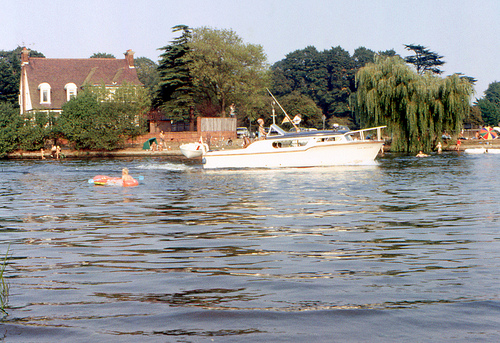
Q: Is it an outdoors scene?
A: Yes, it is outdoors.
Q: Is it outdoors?
A: Yes, it is outdoors.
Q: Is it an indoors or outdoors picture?
A: It is outdoors.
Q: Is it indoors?
A: No, it is outdoors.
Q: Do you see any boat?
A: Yes, there is a boat.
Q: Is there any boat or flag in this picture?
A: Yes, there is a boat.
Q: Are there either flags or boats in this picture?
A: Yes, there is a boat.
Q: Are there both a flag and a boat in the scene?
A: No, there is a boat but no flags.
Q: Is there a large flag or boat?
A: Yes, there is a large boat.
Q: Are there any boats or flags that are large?
A: Yes, the boat is large.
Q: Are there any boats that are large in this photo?
A: Yes, there is a large boat.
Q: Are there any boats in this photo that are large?
A: Yes, there is a boat that is large.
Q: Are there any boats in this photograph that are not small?
A: Yes, there is a large boat.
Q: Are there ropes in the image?
A: No, there are no ropes.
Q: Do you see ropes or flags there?
A: No, there are no ropes or flags.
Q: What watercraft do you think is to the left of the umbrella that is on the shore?
A: The watercraft is a boat.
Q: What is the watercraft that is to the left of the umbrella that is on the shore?
A: The watercraft is a boat.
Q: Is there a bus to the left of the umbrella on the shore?
A: No, there is a boat to the left of the umbrella.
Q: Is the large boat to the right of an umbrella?
A: No, the boat is to the left of an umbrella.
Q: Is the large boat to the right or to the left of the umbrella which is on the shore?
A: The boat is to the left of the umbrella.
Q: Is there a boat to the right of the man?
A: Yes, there is a boat to the right of the man.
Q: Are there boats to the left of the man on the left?
A: No, the boat is to the right of the man.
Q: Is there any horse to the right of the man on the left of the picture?
A: No, there is a boat to the right of the man.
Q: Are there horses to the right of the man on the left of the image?
A: No, there is a boat to the right of the man.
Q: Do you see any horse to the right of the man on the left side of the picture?
A: No, there is a boat to the right of the man.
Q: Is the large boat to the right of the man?
A: Yes, the boat is to the right of the man.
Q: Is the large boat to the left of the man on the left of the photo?
A: No, the boat is to the right of the man.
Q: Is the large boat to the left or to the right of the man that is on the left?
A: The boat is to the right of the man.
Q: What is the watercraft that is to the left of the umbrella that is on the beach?
A: The watercraft is a boat.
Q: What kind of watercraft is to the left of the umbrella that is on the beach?
A: The watercraft is a boat.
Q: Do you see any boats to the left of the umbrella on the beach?
A: Yes, there is a boat to the left of the umbrella.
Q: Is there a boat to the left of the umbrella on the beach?
A: Yes, there is a boat to the left of the umbrella.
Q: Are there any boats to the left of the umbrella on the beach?
A: Yes, there is a boat to the left of the umbrella.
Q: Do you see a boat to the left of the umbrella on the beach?
A: Yes, there is a boat to the left of the umbrella.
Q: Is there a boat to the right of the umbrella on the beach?
A: No, the boat is to the left of the umbrella.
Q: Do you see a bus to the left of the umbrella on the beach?
A: No, there is a boat to the left of the umbrella.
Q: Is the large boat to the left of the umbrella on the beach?
A: Yes, the boat is to the left of the umbrella.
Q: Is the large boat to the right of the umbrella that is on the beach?
A: No, the boat is to the left of the umbrella.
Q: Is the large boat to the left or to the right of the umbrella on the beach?
A: The boat is to the left of the umbrella.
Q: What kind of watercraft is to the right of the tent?
A: The watercraft is a boat.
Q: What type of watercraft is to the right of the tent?
A: The watercraft is a boat.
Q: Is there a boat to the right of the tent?
A: Yes, there is a boat to the right of the tent.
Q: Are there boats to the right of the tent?
A: Yes, there is a boat to the right of the tent.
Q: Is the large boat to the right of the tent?
A: Yes, the boat is to the right of the tent.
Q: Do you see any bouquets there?
A: No, there are no bouquets.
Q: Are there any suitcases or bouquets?
A: No, there are no bouquets or suitcases.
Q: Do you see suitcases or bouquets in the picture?
A: No, there are no bouquets or suitcases.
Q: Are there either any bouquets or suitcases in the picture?
A: No, there are no bouquets or suitcases.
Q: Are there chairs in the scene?
A: No, there are no chairs.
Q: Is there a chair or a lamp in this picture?
A: No, there are no chairs or lamps.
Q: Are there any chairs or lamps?
A: No, there are no chairs or lamps.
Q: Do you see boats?
A: Yes, there is a boat.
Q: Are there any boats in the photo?
A: Yes, there is a boat.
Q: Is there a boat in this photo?
A: Yes, there is a boat.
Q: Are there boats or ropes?
A: Yes, there is a boat.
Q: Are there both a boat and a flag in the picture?
A: No, there is a boat but no flags.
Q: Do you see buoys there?
A: No, there are no buoys.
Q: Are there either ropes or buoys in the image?
A: No, there are no buoys or ropes.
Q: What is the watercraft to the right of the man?
A: The watercraft is a boat.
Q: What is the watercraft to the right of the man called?
A: The watercraft is a boat.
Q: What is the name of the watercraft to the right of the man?
A: The watercraft is a boat.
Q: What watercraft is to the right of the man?
A: The watercraft is a boat.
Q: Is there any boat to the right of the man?
A: Yes, there is a boat to the right of the man.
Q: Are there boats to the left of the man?
A: No, the boat is to the right of the man.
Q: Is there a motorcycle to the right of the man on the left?
A: No, there is a boat to the right of the man.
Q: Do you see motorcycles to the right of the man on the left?
A: No, there is a boat to the right of the man.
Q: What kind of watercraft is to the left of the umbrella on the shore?
A: The watercraft is a boat.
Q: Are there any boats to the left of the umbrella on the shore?
A: Yes, there is a boat to the left of the umbrella.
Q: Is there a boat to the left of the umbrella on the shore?
A: Yes, there is a boat to the left of the umbrella.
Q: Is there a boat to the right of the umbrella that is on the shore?
A: No, the boat is to the left of the umbrella.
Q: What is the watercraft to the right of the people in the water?
A: The watercraft is a boat.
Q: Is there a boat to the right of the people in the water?
A: Yes, there is a boat to the right of the people.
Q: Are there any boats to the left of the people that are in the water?
A: No, the boat is to the right of the people.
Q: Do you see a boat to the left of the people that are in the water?
A: No, the boat is to the right of the people.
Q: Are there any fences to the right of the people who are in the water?
A: No, there is a boat to the right of the people.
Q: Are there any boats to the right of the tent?
A: Yes, there is a boat to the right of the tent.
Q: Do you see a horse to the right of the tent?
A: No, there is a boat to the right of the tent.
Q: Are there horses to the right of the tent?
A: No, there is a boat to the right of the tent.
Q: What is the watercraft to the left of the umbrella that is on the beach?
A: The watercraft is a boat.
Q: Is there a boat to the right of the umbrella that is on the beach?
A: No, the boat is to the left of the umbrella.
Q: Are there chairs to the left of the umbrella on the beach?
A: No, there is a boat to the left of the umbrella.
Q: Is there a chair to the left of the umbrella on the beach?
A: No, there is a boat to the left of the umbrella.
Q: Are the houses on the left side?
A: Yes, the houses are on the left of the image.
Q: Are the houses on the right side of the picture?
A: No, the houses are on the left of the image.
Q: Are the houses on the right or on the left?
A: The houses are on the left of the image.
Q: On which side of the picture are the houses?
A: The houses are on the left of the image.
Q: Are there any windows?
A: Yes, there are windows.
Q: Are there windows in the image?
A: Yes, there are windows.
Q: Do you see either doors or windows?
A: Yes, there are windows.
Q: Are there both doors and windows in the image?
A: No, there are windows but no doors.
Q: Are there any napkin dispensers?
A: No, there are no napkin dispensers.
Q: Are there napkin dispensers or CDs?
A: No, there are no napkin dispensers or cds.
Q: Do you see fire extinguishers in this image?
A: No, there are no fire extinguishers.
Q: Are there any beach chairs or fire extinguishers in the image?
A: No, there are no fire extinguishers or beach chairs.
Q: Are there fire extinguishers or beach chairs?
A: No, there are no fire extinguishers or beach chairs.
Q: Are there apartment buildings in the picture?
A: No, there are no apartment buildings.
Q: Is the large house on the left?
A: Yes, the house is on the left of the image.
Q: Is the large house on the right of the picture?
A: No, the house is on the left of the image.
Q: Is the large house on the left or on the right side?
A: The house is on the left of the image.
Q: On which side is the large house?
A: The house is on the left of the image.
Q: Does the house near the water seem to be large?
A: Yes, the house is large.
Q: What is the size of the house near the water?
A: The house is large.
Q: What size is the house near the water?
A: The house is large.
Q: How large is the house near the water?
A: The house is large.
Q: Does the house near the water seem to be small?
A: No, the house is large.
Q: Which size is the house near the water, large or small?
A: The house is large.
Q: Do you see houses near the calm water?
A: Yes, there is a house near the water.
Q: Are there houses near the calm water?
A: Yes, there is a house near the water.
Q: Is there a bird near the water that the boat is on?
A: No, there is a house near the water.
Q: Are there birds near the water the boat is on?
A: No, there is a house near the water.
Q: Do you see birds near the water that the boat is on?
A: No, there is a house near the water.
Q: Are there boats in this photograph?
A: Yes, there is a boat.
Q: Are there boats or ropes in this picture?
A: Yes, there is a boat.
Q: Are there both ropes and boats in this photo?
A: No, there is a boat but no ropes.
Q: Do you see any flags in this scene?
A: No, there are no flags.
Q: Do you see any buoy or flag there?
A: No, there are no flags or buoys.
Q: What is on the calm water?
A: The boat is on the water.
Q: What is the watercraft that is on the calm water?
A: The watercraft is a boat.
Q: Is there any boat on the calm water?
A: Yes, there is a boat on the water.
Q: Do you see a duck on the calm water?
A: No, there is a boat on the water.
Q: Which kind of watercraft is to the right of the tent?
A: The watercraft is a boat.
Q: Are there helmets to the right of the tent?
A: No, there is a boat to the right of the tent.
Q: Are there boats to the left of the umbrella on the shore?
A: Yes, there is a boat to the left of the umbrella.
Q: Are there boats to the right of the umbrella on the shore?
A: No, the boat is to the left of the umbrella.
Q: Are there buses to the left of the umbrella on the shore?
A: No, there is a boat to the left of the umbrella.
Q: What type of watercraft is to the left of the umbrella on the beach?
A: The watercraft is a boat.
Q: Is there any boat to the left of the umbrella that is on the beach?
A: Yes, there is a boat to the left of the umbrella.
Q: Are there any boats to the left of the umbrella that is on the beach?
A: Yes, there is a boat to the left of the umbrella.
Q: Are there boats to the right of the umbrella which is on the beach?
A: No, the boat is to the left of the umbrella.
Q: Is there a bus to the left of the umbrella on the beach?
A: No, there is a boat to the left of the umbrella.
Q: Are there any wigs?
A: No, there are no wigs.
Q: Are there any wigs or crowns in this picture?
A: No, there are no wigs or crowns.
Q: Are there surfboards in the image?
A: No, there are no surfboards.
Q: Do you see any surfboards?
A: No, there are no surfboards.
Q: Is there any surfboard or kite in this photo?
A: No, there are no surfboards or kites.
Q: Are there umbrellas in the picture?
A: Yes, there is an umbrella.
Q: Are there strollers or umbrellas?
A: Yes, there is an umbrella.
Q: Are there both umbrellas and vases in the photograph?
A: No, there is an umbrella but no vases.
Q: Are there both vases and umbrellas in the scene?
A: No, there is an umbrella but no vases.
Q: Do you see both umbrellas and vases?
A: No, there is an umbrella but no vases.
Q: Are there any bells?
A: No, there are no bells.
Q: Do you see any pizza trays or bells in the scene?
A: No, there are no bells or pizza trays.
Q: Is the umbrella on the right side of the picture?
A: Yes, the umbrella is on the right of the image.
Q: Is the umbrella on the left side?
A: No, the umbrella is on the right of the image.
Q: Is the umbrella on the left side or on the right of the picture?
A: The umbrella is on the right of the image.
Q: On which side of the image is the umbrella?
A: The umbrella is on the right of the image.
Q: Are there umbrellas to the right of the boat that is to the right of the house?
A: Yes, there is an umbrella to the right of the boat.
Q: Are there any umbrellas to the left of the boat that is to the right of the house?
A: No, the umbrella is to the right of the boat.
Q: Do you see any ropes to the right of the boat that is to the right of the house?
A: No, there is an umbrella to the right of the boat.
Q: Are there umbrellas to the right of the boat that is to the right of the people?
A: Yes, there is an umbrella to the right of the boat.